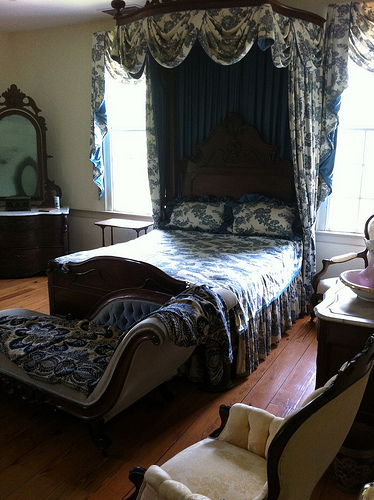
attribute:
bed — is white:
[48, 196, 332, 369]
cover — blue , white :
[54, 224, 308, 378]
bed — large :
[42, 1, 334, 393]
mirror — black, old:
[3, 84, 57, 210]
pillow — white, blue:
[226, 199, 297, 239]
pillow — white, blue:
[165, 198, 225, 230]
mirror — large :
[7, 96, 57, 224]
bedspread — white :
[61, 205, 302, 307]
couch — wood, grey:
[0, 283, 227, 486]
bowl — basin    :
[329, 236, 372, 312]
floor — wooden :
[1, 274, 317, 498]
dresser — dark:
[0, 206, 69, 278]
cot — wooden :
[76, 170, 347, 371]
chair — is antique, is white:
[132, 343, 370, 494]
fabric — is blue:
[164, 237, 273, 262]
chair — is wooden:
[2, 300, 238, 431]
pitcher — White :
[349, 217, 362, 282]